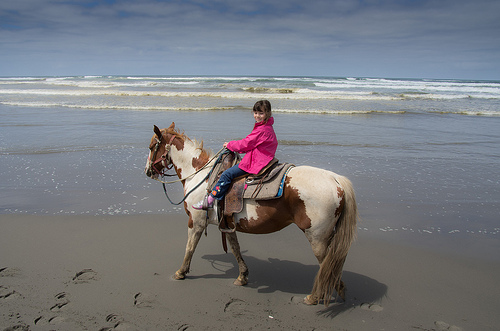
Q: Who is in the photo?
A: A woman.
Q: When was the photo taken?
A: Daytime.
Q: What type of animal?
A: Horse.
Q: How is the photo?
A: Clear.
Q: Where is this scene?
A: A beach.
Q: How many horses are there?
A: One.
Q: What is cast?
A: Shadow.